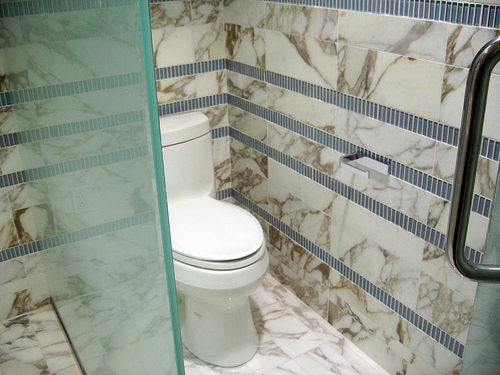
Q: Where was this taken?
A: Bathroom.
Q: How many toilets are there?
A: 1.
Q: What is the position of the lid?
A: Down.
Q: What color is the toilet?
A: White.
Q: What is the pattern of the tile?
A: Marble.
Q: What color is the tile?
A: Brown, gray and white.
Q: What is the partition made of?
A: Glass.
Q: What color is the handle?
A: Silver.